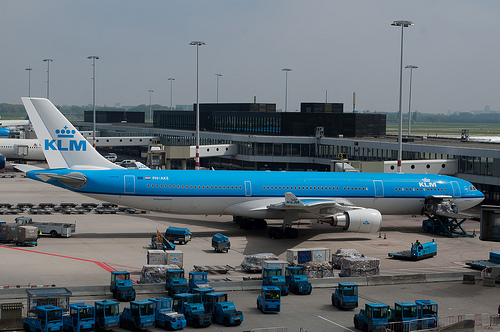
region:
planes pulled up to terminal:
[1, 94, 488, 241]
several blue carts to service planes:
[25, 227, 499, 330]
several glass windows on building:
[67, 102, 497, 194]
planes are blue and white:
[1, 97, 484, 225]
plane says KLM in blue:
[41, 126, 92, 157]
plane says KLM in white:
[419, 173, 437, 188]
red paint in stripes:
[0, 231, 497, 289]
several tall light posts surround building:
[23, 20, 418, 142]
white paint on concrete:
[316, 229, 398, 329]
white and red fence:
[362, 310, 499, 330]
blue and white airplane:
[16, 95, 483, 232]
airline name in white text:
[418, 176, 436, 188]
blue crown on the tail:
[56, 125, 78, 140]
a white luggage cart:
[288, 247, 333, 266]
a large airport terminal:
[69, 117, 496, 184]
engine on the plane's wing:
[325, 208, 383, 233]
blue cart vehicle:
[331, 281, 359, 307]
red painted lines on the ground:
[2, 243, 132, 282]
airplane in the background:
[0, 138, 50, 160]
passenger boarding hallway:
[332, 159, 354, 174]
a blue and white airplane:
[10, 94, 488, 244]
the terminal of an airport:
[80, 113, 491, 167]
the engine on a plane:
[328, 207, 392, 232]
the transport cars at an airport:
[32, 262, 440, 329]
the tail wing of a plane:
[32, 167, 89, 185]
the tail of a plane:
[19, 92, 124, 172]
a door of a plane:
[118, 172, 138, 197]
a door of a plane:
[371, 174, 387, 201]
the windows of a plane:
[143, 180, 244, 195]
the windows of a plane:
[258, 182, 368, 192]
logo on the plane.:
[46, 129, 76, 157]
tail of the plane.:
[15, 96, 55, 121]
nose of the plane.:
[472, 187, 484, 203]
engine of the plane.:
[332, 208, 382, 229]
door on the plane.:
[242, 179, 254, 196]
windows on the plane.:
[304, 180, 336, 192]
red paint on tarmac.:
[60, 250, 106, 271]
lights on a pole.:
[385, 11, 416, 35]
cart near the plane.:
[210, 233, 231, 253]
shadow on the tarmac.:
[255, 235, 281, 247]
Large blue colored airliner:
[10, 93, 498, 238]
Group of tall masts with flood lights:
[12, 17, 436, 172]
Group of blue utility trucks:
[8, 225, 499, 330]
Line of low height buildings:
[81, 98, 497, 214]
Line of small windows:
[141, 180, 451, 192]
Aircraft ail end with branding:
[9, 90, 126, 200]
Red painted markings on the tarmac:
[1, 240, 141, 288]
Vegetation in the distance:
[360, 106, 499, 125]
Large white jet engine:
[313, 203, 386, 235]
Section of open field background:
[381, 121, 497, 134]